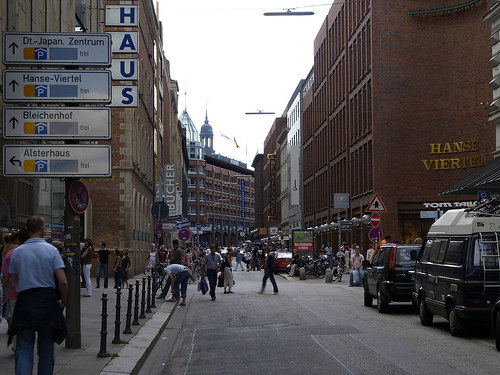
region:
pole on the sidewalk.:
[97, 295, 111, 368]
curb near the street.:
[134, 333, 156, 368]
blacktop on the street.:
[258, 343, 295, 368]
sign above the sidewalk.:
[0, 153, 97, 189]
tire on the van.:
[413, 293, 427, 328]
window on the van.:
[446, 243, 462, 259]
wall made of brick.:
[400, 35, 428, 89]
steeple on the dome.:
[197, 102, 209, 125]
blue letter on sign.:
[118, 60, 138, 77]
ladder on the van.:
[482, 235, 498, 295]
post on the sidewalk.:
[98, 292, 115, 358]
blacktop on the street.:
[218, 333, 262, 369]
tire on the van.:
[450, 303, 458, 335]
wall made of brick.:
[397, 100, 414, 139]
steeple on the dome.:
[200, 95, 212, 119]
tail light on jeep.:
[387, 245, 395, 270]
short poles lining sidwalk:
[95, 252, 195, 359]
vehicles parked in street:
[346, 197, 498, 362]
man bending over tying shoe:
[152, 234, 210, 329]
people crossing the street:
[214, 242, 338, 309]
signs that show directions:
[4, 18, 124, 211]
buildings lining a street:
[224, 10, 482, 290]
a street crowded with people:
[148, 223, 365, 318]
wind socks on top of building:
[213, 125, 265, 206]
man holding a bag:
[337, 235, 392, 299]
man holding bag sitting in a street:
[341, 232, 374, 294]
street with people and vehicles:
[180, 262, 462, 367]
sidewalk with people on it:
[29, 280, 131, 364]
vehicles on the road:
[365, 209, 499, 331]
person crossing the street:
[256, 250, 287, 288]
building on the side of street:
[248, 58, 498, 245]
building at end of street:
[190, 157, 257, 245]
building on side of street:
[3, 9, 169, 274]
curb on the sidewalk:
[102, 313, 172, 365]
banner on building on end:
[230, 180, 247, 225]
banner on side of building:
[158, 158, 180, 218]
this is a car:
[362, 240, 418, 302]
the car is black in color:
[352, 276, 393, 293]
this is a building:
[300, 35, 496, 207]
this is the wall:
[383, 34, 471, 122]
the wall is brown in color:
[395, 29, 457, 110]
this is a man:
[27, 223, 59, 348]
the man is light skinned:
[58, 268, 70, 295]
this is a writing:
[418, 137, 491, 180]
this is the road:
[231, 287, 328, 371]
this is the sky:
[180, 21, 279, 120]